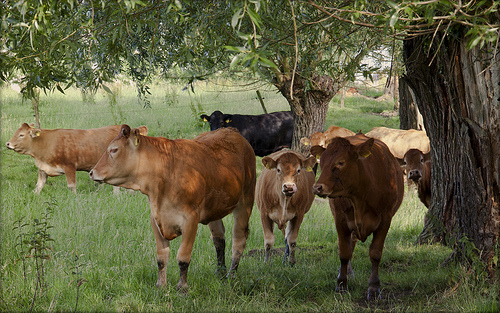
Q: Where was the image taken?
A: It was taken at the pasture.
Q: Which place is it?
A: It is a pasture.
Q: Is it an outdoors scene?
A: Yes, it is outdoors.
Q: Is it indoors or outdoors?
A: It is outdoors.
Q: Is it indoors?
A: No, it is outdoors.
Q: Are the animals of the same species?
A: Yes, all the animals are cows.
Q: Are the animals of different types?
A: No, all the animals are cows.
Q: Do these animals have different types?
A: No, all the animals are cows.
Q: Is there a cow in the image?
A: Yes, there is a cow.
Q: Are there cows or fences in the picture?
A: Yes, there is a cow.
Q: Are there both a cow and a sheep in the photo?
A: No, there is a cow but no sheep.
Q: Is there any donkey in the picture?
A: No, there are no donkeys.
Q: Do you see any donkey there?
A: No, there are no donkeys.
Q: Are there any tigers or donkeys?
A: No, there are no donkeys or tigers.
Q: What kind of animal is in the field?
A: The animal is a cow.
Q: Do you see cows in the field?
A: Yes, there is a cow in the field.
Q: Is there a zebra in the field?
A: No, there is a cow in the field.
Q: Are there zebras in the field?
A: No, there is a cow in the field.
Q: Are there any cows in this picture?
A: Yes, there is a cow.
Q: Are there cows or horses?
A: Yes, there is a cow.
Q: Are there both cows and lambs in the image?
A: No, there is a cow but no lambs.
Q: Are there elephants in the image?
A: No, there are no elephants.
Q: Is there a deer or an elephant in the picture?
A: No, there are no elephants or deer.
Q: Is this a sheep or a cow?
A: This is a cow.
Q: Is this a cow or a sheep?
A: This is a cow.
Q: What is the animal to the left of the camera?
A: The animal is a cow.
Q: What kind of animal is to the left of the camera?
A: The animal is a cow.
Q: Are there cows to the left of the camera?
A: Yes, there is a cow to the left of the camera.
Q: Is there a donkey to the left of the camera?
A: No, there is a cow to the left of the camera.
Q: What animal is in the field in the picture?
A: The cow is in the field.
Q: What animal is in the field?
A: The cow is in the field.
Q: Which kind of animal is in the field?
A: The animal is a cow.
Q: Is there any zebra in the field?
A: No, there is a cow in the field.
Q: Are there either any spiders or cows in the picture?
A: Yes, there is a cow.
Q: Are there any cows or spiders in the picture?
A: Yes, there is a cow.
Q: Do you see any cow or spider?
A: Yes, there is a cow.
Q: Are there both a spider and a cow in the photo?
A: No, there is a cow but no spiders.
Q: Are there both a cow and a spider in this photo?
A: No, there is a cow but no spiders.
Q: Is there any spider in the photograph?
A: No, there are no spiders.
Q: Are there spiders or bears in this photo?
A: No, there are no spiders or bears.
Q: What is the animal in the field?
A: The animal is a cow.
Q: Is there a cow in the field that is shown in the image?
A: Yes, there is a cow in the field.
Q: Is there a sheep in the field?
A: No, there is a cow in the field.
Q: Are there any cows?
A: Yes, there is a cow.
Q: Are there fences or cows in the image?
A: Yes, there is a cow.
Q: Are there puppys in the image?
A: No, there are no puppys.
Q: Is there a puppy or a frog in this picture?
A: No, there are no puppys or frogs.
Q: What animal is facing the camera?
A: The cow is facing the camera.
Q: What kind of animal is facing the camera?
A: The animal is a cow.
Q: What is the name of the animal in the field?
A: The animal is a cow.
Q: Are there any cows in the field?
A: Yes, there is a cow in the field.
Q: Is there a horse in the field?
A: No, there is a cow in the field.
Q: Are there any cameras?
A: Yes, there is a camera.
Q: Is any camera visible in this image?
A: Yes, there is a camera.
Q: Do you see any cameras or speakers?
A: Yes, there is a camera.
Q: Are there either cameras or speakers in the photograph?
A: Yes, there is a camera.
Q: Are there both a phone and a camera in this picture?
A: No, there is a camera but no phones.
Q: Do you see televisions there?
A: No, there are no televisions.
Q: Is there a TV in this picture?
A: No, there are no televisions.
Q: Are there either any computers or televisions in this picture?
A: No, there are no televisions or computers.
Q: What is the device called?
A: The device is a camera.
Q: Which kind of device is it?
A: The device is a camera.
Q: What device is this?
A: That is a camera.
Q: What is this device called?
A: That is a camera.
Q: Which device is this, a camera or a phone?
A: That is a camera.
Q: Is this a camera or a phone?
A: This is a camera.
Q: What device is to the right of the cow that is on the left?
A: The device is a camera.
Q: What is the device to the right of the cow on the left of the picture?
A: The device is a camera.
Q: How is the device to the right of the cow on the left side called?
A: The device is a camera.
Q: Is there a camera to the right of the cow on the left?
A: Yes, there is a camera to the right of the cow.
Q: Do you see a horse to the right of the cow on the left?
A: No, there is a camera to the right of the cow.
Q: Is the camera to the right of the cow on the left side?
A: Yes, the camera is to the right of the cow.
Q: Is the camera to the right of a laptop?
A: No, the camera is to the right of the cow.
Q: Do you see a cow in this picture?
A: Yes, there is a cow.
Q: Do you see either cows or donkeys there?
A: Yes, there is a cow.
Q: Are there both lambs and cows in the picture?
A: No, there is a cow but no lambs.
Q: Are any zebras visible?
A: No, there are no zebras.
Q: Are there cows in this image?
A: Yes, there is a cow.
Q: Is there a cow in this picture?
A: Yes, there is a cow.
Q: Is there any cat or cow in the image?
A: Yes, there is a cow.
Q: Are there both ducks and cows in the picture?
A: No, there is a cow but no ducks.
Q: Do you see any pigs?
A: No, there are no pigs.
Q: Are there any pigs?
A: No, there are no pigs.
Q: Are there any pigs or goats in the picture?
A: No, there are no pigs or goats.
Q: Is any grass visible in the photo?
A: Yes, there is grass.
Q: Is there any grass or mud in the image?
A: Yes, there is grass.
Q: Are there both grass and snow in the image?
A: No, there is grass but no snow.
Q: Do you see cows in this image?
A: Yes, there is a cow.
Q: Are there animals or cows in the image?
A: Yes, there is a cow.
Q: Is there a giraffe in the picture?
A: No, there are no giraffes.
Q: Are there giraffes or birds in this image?
A: No, there are no giraffes or birds.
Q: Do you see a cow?
A: Yes, there is a cow.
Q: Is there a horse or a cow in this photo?
A: Yes, there is a cow.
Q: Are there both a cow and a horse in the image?
A: No, there is a cow but no horses.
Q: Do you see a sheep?
A: No, there is no sheep.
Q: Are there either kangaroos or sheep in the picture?
A: No, there are no sheep or kangaroos.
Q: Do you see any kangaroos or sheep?
A: No, there are no sheep or kangaroos.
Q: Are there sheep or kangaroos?
A: No, there are no sheep or kangaroos.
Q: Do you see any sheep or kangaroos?
A: No, there are no sheep or kangaroos.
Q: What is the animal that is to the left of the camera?
A: The animal is a cow.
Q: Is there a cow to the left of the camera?
A: Yes, there is a cow to the left of the camera.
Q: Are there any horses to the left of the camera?
A: No, there is a cow to the left of the camera.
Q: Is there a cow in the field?
A: Yes, there is a cow in the field.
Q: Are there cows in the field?
A: Yes, there is a cow in the field.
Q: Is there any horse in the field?
A: No, there is a cow in the field.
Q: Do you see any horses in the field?
A: No, there is a cow in the field.